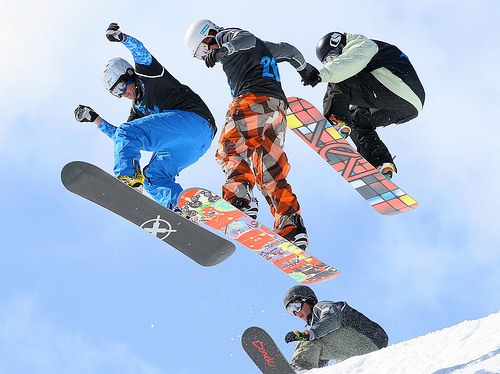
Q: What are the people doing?
A: Snowboarding.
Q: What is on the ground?
A: Snow.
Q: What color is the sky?
A: Blue.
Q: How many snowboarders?
A: Four.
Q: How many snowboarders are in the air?
A: Three.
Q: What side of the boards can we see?
A: The bottom.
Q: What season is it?
A: Winter.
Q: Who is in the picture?
A: Snowboarders.